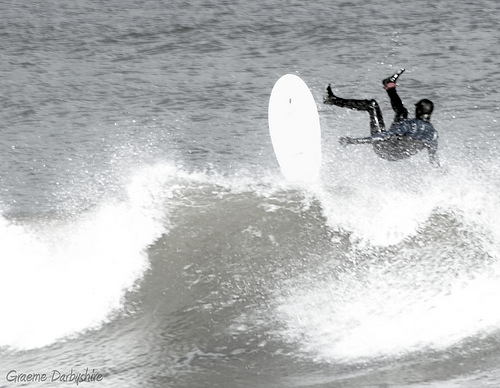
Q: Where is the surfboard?
A: Next to the surfer.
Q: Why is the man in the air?
A: He fell off the surfboard.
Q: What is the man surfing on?
A: A wave.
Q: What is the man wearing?
A: A wetsuit.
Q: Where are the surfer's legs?
A: In the air.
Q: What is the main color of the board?
A: White.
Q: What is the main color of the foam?
A: White.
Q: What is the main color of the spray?
A: White.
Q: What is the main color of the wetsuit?
A: Black.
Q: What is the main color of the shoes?
A: Black.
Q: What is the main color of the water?
A: Gray.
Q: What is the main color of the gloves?
A: Black.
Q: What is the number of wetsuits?
A: One.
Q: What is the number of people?
A: One.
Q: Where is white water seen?
A: White water is seen on the wave.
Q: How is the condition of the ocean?
A: The ocean has small swells and ripples.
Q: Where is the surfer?
A: The surfer is flying through the air.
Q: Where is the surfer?
A: The surfer fell off the surfboard.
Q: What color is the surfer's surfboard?
A: The surfer's surfboard is white.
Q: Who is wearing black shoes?
A: The surfer is wearing black shoes.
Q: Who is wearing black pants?
A: The surfer is wearing black pants.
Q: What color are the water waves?
A: The color waves of water are grey.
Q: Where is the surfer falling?
A: Into the water.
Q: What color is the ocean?
A: Gray.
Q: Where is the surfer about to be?
A: In the water.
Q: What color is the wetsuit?
A: Black.